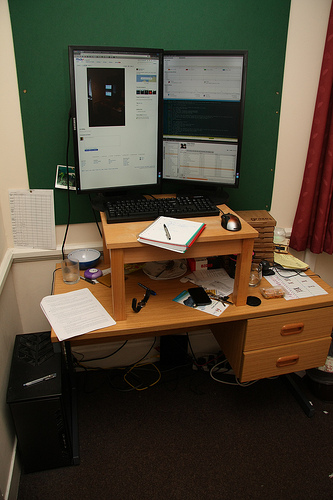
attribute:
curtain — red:
[288, 0, 332, 254]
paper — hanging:
[5, 188, 58, 252]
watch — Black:
[128, 294, 147, 308]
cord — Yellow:
[119, 359, 167, 391]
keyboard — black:
[105, 194, 222, 220]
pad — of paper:
[133, 211, 205, 258]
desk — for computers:
[90, 214, 251, 253]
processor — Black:
[6, 324, 84, 478]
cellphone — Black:
[187, 285, 211, 305]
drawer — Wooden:
[235, 315, 329, 371]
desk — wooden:
[33, 243, 332, 390]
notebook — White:
[137, 209, 207, 254]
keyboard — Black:
[103, 193, 219, 224]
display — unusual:
[65, 40, 246, 223]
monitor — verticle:
[66, 40, 162, 199]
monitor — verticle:
[163, 48, 244, 193]